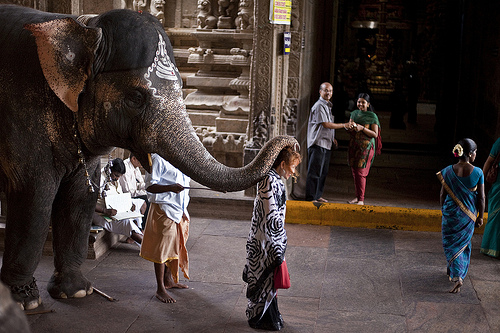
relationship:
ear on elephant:
[32, 9, 103, 109] [3, 1, 296, 324]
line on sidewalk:
[280, 198, 437, 230] [311, 150, 445, 210]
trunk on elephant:
[159, 110, 302, 193] [3, 1, 296, 324]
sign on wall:
[266, 0, 294, 26] [264, 1, 311, 141]